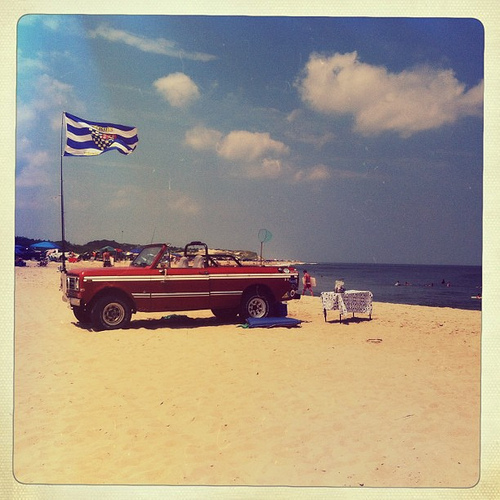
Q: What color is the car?
A: Red and white.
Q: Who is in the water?
A: Swimmers.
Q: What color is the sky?
A: Blue.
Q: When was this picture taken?
A: Daytime.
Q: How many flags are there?
A: One.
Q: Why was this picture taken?
A: To show the car.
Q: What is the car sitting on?
A: Sand.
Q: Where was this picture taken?
A: At the beach.